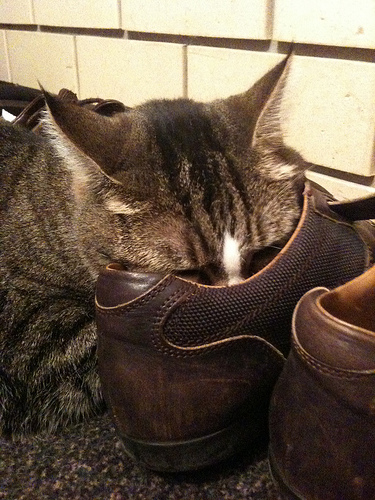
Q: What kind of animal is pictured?
A: Cat.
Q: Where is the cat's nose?
A: In the shoe.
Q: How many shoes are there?
A: 2.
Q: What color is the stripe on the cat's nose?
A: White.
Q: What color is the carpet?
A: Gray.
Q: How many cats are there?
A: 1.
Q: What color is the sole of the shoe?
A: Black.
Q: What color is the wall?
A: White.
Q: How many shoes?
A: Two.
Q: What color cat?
A: Black, gray and white.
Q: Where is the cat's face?
A: In shoe.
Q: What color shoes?
A: Brown.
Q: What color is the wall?
A: Black and white.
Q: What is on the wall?
A: Tile.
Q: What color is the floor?
A: Gray.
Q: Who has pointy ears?
A: The cat.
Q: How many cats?
A: One.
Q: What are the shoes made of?
A: Leather.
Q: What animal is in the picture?
A: Cat.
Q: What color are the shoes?
A: Brown.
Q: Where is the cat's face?
A: In a shoe.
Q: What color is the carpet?
A: Black.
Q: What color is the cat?
A: Black, brown and white.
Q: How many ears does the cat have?
A: Two.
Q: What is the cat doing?
A: Sleeping.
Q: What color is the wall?
A: White.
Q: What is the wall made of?
A: Tile.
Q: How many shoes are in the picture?
A: Two.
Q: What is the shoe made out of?
A: Leather.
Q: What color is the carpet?
A: Scrubber brown.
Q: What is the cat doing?
A: Smelling.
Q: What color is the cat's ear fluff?
A: White.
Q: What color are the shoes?
A: Brown.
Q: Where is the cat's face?
A: In a shoe.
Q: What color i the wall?
A: White.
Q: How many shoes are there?
A: Two.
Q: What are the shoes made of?
A: Leather.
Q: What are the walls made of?
A: Brick.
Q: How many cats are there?
A: One.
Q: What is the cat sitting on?
A: Carpet.